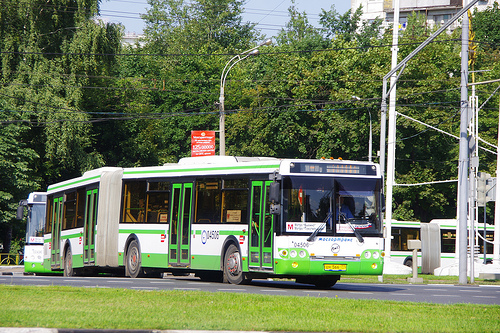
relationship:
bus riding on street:
[44, 155, 385, 285] [0, 274, 498, 306]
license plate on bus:
[323, 264, 346, 272] [44, 155, 385, 285]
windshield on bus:
[277, 175, 334, 236] [44, 155, 385, 285]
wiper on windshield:
[305, 210, 332, 242] [277, 175, 334, 236]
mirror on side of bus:
[269, 181, 281, 206] [44, 155, 385, 285]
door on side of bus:
[168, 182, 182, 266] [44, 155, 385, 285]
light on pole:
[264, 39, 272, 46] [220, 37, 271, 155]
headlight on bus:
[295, 250, 309, 262] [44, 155, 385, 285]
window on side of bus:
[218, 189, 250, 223] [44, 155, 385, 285]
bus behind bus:
[12, 191, 49, 276] [44, 155, 385, 285]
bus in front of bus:
[44, 155, 385, 285] [12, 191, 49, 276]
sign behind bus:
[190, 131, 215, 157] [44, 155, 385, 285]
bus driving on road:
[44, 155, 385, 285] [1, 274, 498, 307]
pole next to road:
[220, 37, 271, 155] [1, 274, 498, 307]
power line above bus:
[2, 90, 464, 106] [44, 155, 385, 285]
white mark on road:
[389, 292, 416, 298] [1, 274, 498, 307]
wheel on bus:
[223, 242, 248, 286] [44, 155, 385, 285]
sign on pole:
[190, 131, 215, 157] [220, 37, 271, 155]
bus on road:
[44, 155, 385, 285] [1, 274, 498, 307]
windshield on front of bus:
[333, 177, 384, 234] [44, 155, 385, 285]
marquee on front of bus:
[298, 164, 366, 175] [44, 155, 385, 285]